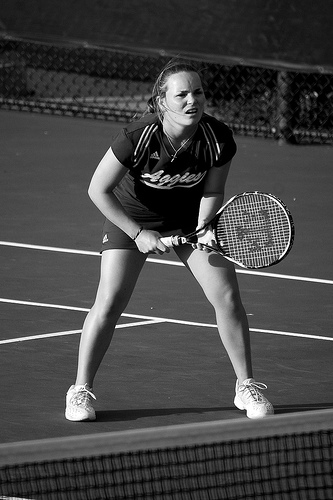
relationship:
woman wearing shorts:
[63, 60, 277, 422] [100, 201, 231, 250]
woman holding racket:
[63, 54, 299, 422] [158, 189, 295, 271]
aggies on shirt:
[141, 167, 205, 193] [109, 109, 236, 219]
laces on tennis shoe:
[235, 380, 267, 401] [230, 375, 275, 419]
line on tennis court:
[0, 319, 161, 361] [2, 114, 329, 405]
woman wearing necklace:
[63, 60, 277, 422] [156, 119, 203, 166]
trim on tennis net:
[1, 411, 329, 461] [2, 403, 331, 497]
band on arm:
[129, 228, 151, 243] [85, 124, 144, 243]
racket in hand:
[147, 145, 302, 294] [128, 222, 170, 258]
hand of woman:
[128, 222, 170, 258] [63, 60, 277, 422]